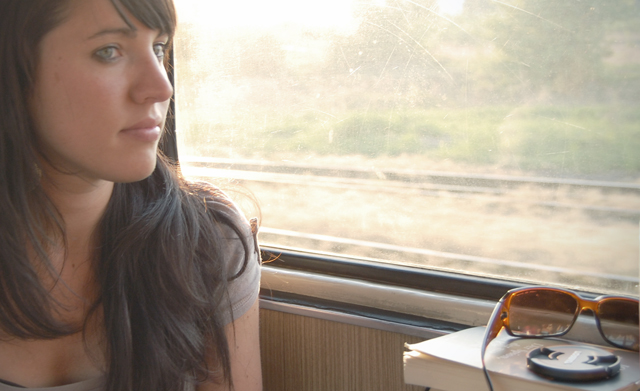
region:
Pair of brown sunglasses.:
[475, 275, 638, 388]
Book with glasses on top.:
[393, 287, 638, 389]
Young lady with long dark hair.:
[3, 0, 269, 387]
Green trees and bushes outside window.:
[303, 5, 628, 181]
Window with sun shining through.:
[169, 3, 637, 311]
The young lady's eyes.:
[90, 22, 179, 61]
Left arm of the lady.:
[198, 178, 265, 388]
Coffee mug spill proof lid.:
[524, 342, 619, 380]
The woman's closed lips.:
[108, 109, 171, 150]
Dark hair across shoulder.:
[96, 168, 262, 385]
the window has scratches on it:
[372, 0, 463, 93]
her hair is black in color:
[128, 194, 183, 273]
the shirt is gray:
[230, 250, 259, 298]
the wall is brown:
[296, 344, 361, 369]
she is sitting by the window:
[153, 19, 239, 240]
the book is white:
[421, 335, 462, 379]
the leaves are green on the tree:
[546, 19, 583, 62]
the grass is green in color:
[571, 127, 608, 163]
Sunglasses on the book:
[473, 278, 637, 388]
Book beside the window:
[385, 312, 636, 389]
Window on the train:
[168, 3, 638, 348]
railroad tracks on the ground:
[186, 147, 634, 222]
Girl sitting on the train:
[0, 2, 256, 385]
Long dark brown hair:
[1, 0, 257, 390]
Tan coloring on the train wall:
[202, 295, 436, 389]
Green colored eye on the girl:
[82, 34, 132, 67]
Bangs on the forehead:
[92, 0, 182, 42]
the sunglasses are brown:
[480, 285, 638, 389]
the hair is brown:
[0, 0, 269, 388]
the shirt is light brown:
[1, 193, 258, 387]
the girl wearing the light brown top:
[0, 2, 263, 388]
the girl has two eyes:
[0, 1, 260, 388]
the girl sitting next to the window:
[0, 1, 638, 386]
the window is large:
[170, 0, 639, 297]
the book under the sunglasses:
[402, 281, 635, 388]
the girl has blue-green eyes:
[0, 0, 266, 390]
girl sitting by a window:
[6, 7, 326, 386]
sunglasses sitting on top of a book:
[472, 279, 636, 388]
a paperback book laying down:
[399, 318, 622, 388]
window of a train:
[215, 23, 624, 264]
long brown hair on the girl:
[106, 197, 222, 382]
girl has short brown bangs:
[109, 1, 177, 36]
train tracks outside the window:
[314, 157, 587, 212]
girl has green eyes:
[82, 28, 174, 61]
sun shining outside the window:
[234, 8, 415, 91]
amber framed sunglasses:
[474, 269, 634, 373]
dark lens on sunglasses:
[507, 292, 570, 332]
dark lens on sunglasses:
[599, 300, 639, 344]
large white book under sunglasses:
[389, 320, 636, 387]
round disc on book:
[523, 341, 618, 383]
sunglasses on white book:
[478, 279, 631, 389]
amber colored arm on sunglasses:
[480, 300, 504, 388]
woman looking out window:
[9, 1, 181, 190]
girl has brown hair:
[0, 51, 224, 361]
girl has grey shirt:
[135, 161, 290, 385]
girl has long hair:
[1, 2, 262, 364]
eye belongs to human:
[92, 41, 121, 62]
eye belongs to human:
[148, 41, 169, 57]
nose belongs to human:
[127, 54, 173, 105]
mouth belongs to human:
[112, 119, 164, 144]